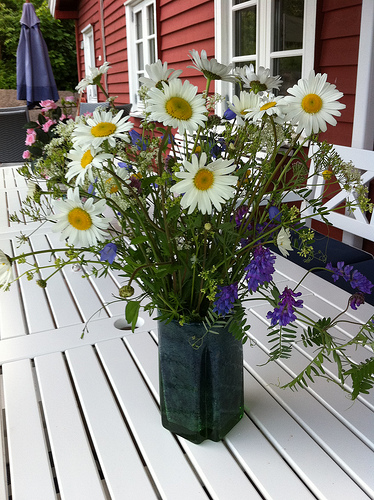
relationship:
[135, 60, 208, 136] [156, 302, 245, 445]
flowers in vase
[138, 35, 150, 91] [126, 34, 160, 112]
window has trim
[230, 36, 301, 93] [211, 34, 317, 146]
window has trim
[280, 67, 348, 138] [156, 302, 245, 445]
flower in vase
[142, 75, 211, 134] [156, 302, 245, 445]
flower in vase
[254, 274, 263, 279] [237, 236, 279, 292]
petals on flower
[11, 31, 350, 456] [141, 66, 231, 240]
bouquet of flowers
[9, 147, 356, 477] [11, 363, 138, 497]
table of planks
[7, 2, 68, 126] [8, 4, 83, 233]
umbrella on side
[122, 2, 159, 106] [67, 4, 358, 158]
window on building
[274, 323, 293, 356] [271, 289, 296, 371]
leaf on flower